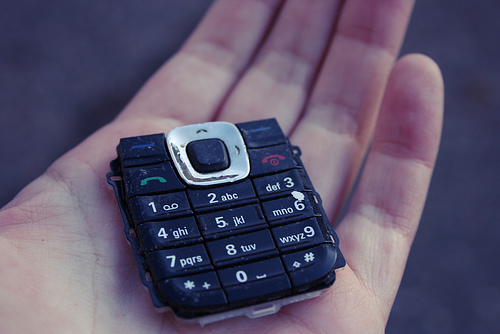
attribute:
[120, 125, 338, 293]
keypad — black, broken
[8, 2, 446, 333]
hand — human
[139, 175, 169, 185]
phone handset — green, call button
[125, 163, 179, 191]
button — black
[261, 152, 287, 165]
phone handset — red, end call button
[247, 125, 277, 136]
line — blue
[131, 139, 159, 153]
line — blue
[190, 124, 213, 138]
arrow — silver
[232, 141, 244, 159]
arrow — silver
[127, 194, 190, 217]
button — black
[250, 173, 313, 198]
button — black